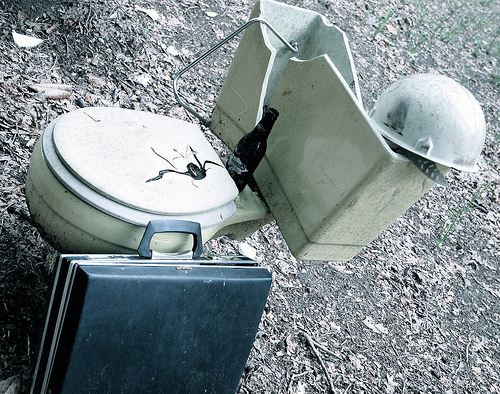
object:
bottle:
[224, 107, 280, 193]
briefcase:
[28, 219, 271, 394]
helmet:
[368, 73, 486, 186]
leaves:
[239, 190, 500, 394]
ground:
[0, 0, 500, 394]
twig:
[299, 332, 337, 394]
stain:
[145, 145, 224, 189]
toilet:
[0, 0, 500, 394]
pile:
[25, 0, 486, 394]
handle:
[137, 219, 203, 259]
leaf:
[28, 84, 72, 100]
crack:
[255, 50, 295, 127]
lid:
[52, 106, 240, 216]